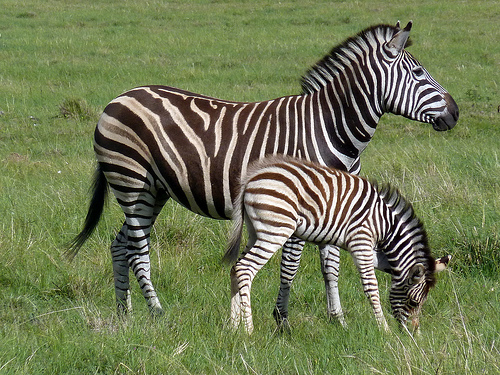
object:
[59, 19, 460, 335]
zebra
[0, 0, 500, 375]
grass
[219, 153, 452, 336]
zebra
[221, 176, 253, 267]
tail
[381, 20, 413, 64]
ear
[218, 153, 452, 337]
fur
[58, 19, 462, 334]
fur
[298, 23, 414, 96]
mane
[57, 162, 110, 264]
tail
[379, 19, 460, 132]
head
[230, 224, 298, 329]
leg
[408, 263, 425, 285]
ear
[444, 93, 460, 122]
nose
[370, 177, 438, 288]
mane